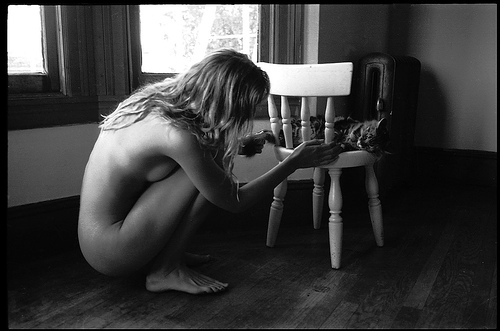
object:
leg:
[327, 168, 343, 270]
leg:
[364, 162, 384, 246]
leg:
[312, 164, 325, 230]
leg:
[265, 178, 286, 248]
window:
[139, 3, 259, 73]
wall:
[402, 0, 500, 157]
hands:
[293, 138, 343, 169]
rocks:
[380, 257, 500, 330]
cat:
[243, 117, 399, 158]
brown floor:
[0, 179, 500, 331]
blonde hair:
[98, 48, 270, 201]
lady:
[77, 48, 343, 294]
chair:
[254, 60, 384, 269]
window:
[7, 4, 45, 76]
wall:
[10, 0, 400, 212]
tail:
[244, 128, 273, 158]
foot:
[145, 265, 228, 295]